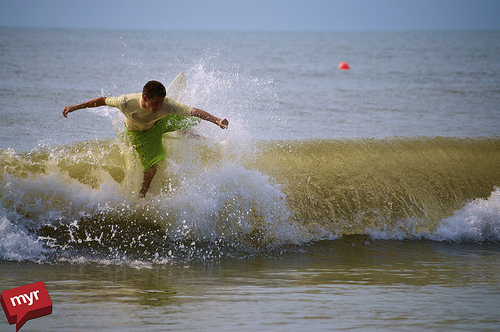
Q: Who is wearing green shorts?
A: Boy in the water.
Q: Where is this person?
A: In the wave.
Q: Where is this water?
A: In the air.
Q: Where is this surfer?
A: In the ocean.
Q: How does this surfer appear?
A: Bending over.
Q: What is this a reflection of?
A: A person.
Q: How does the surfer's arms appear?
A: Extended.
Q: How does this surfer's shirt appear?
A: Yellow in color.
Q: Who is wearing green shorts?
A: The surfer.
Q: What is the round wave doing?
A: Crashing.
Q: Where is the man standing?
A: In a wave.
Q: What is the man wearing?
A: Green shorts and a white shirt.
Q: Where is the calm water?
A: In front of the wave.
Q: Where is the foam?
A: Around the crashing wave.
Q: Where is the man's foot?
A: Near the spraying water.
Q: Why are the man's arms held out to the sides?
A: For balance.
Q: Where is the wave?
A: In the water.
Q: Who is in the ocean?
A: A boy.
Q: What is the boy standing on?
A: A surfboard.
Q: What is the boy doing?
A: Surfing.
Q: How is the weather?
A: Sunny.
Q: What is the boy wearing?
A: Shorts.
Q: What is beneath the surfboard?
A: The wave.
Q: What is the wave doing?
A: Rolling.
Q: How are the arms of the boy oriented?
A: Outstretched.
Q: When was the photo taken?
A: During the daytime.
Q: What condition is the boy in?
A: Wet.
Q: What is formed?
A: Waves.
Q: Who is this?
A: Boy.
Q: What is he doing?
A: Jumping.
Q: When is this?
A: Daytime.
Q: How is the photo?
A: Clear.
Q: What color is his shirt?
A: Yellow.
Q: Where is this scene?
A: In the ocean.